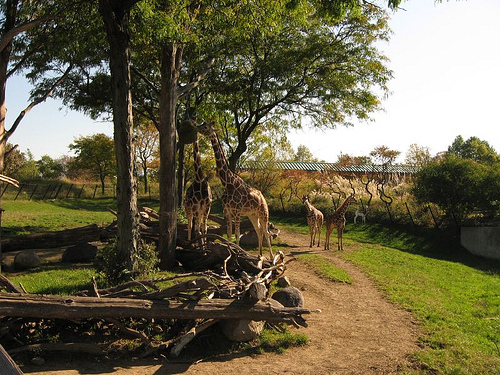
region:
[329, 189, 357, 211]
neck of a giraffe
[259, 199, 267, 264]
leg of a giraffe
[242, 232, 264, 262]
leg of a giraffe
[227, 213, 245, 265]
leg of a giraffe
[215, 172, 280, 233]
body of a giraffe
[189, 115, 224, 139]
head of a giraffe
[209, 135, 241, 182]
neck of a giraffe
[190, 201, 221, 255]
leg of a giraffe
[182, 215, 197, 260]
leg of a giraffe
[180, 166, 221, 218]
body of a giraffe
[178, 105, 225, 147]
The giraffe is eating the leaves.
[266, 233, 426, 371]
The animals have worn a path on the ground.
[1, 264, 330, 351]
The tree has fallen.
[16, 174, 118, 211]
The fence is leaning.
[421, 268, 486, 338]
The grass is green.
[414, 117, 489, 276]
The tree is green and fully in leaf.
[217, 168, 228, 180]
The spot is brown.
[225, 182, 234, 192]
The spot is brown.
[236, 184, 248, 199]
The spot is brown.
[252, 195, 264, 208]
The spot is brown.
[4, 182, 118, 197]
a black fence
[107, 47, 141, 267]
a tree trunk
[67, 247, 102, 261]
large rocks on the ground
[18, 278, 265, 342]
logs on the ground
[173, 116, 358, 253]
giraffes walking on the ground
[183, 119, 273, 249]
two giraffes eating from the tree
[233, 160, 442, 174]
the roof on a building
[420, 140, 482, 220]
trees behind the black fence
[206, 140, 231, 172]
the neck of the giraffe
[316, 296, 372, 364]
dirt and rocks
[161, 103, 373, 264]
a group of giraffes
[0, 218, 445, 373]
dirt path on the ground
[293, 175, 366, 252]
two baby giraffes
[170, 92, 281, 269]
two adult giraffes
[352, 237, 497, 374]
green grass on the ground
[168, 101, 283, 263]
two giraffes eating out of a tree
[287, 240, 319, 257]
shadow on the ground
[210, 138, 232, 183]
dark spots along the neck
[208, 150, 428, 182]
roof of a building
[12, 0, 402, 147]
green leaves on the tree branches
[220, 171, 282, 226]
body of a giraffe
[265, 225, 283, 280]
leg of a giraffe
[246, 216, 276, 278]
leg of a giraffe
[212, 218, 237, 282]
leg of a giraffe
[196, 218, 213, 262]
leg of a giraffe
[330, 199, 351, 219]
neck of a giraffe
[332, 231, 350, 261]
leg of a giraffe